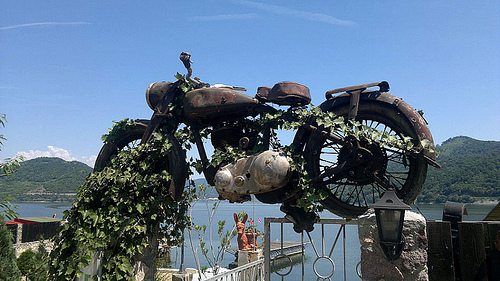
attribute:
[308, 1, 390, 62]
clouds — thin, wispy, white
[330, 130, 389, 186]
wheel — center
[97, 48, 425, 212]
motorcycle — old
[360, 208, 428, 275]
stone fence — small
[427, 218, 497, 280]
fence — wooden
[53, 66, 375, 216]
motorcycle — rusted, old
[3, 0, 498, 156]
sky — open, blue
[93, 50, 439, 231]
motorbike — old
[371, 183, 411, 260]
lantern — old fashioned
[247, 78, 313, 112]
seat — leather, old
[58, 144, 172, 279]
leaves — green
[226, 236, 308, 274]
dock — pontoon, small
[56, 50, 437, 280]
entryway — arched, decorative, old motorcycle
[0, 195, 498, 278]
water — blue, calm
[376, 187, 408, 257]
lamp — black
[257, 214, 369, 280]
gate — metal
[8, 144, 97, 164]
clouds — fluffy, white